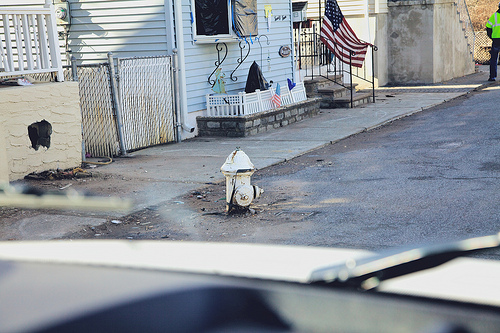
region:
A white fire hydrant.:
[220, 149, 265, 213]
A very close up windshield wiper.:
[307, 234, 499, 289]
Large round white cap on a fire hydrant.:
[231, 185, 253, 208]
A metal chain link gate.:
[103, 53, 184, 157]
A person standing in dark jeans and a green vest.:
[486, 3, 498, 81]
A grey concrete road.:
[118, 82, 498, 262]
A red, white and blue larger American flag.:
[315, 1, 372, 69]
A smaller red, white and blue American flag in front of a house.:
[271, 82, 280, 109]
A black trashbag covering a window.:
[193, 1, 230, 38]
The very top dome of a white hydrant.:
[221, 148, 253, 173]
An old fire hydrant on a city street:
[214, 145, 264, 215]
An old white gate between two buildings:
[61, 55, 183, 155]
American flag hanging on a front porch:
[317, 0, 374, 66]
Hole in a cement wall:
[23, 118, 60, 153]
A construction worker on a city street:
[476, 3, 498, 87]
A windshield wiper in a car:
[293, 233, 498, 297]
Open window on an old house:
[190, 2, 238, 46]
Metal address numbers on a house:
[270, 12, 290, 22]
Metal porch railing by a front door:
[293, 25, 375, 109]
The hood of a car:
[1, 232, 498, 310]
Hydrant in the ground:
[208, 143, 274, 218]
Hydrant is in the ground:
[215, 145, 271, 215]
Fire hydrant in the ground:
[210, 140, 270, 215]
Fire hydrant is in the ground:
[211, 140, 271, 220]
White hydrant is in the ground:
[210, 136, 270, 216]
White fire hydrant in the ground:
[211, 135, 276, 218]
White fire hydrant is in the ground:
[210, 142, 274, 220]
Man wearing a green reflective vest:
[482, 6, 497, 43]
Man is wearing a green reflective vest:
[484, 7, 499, 44]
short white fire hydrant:
[220, 145, 265, 215]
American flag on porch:
[318, 0, 367, 68]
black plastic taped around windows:
[192, 1, 259, 46]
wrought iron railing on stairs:
[299, 31, 358, 98]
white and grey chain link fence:
[69, 53, 182, 163]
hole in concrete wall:
[27, 116, 53, 154]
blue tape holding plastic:
[236, 30, 255, 45]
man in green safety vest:
[484, 5, 499, 84]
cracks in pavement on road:
[427, 143, 491, 195]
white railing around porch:
[2, 6, 66, 86]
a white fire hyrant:
[187, 122, 316, 227]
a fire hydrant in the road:
[159, 122, 359, 268]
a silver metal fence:
[35, 35, 222, 175]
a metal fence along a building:
[42, 53, 256, 170]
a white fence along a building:
[207, 70, 329, 118]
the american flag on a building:
[305, 0, 391, 85]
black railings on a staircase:
[299, 16, 386, 108]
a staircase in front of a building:
[282, 13, 395, 99]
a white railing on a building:
[4, 0, 111, 182]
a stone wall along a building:
[175, 95, 350, 135]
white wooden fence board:
[3, 16, 15, 70]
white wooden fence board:
[9, 10, 26, 70]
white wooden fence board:
[22, 9, 37, 74]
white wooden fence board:
[1, 7, 48, 12]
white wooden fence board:
[1, 65, 54, 77]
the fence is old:
[117, 54, 179, 149]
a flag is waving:
[321, 4, 363, 65]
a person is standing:
[485, 7, 499, 78]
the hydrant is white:
[223, 146, 258, 212]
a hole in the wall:
[25, 119, 54, 150]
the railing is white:
[0, 1, 60, 76]